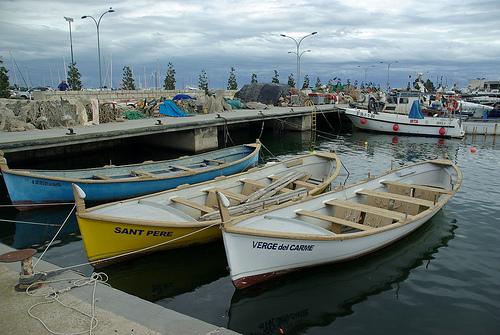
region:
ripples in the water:
[414, 245, 499, 307]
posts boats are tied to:
[7, 244, 51, 291]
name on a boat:
[98, 219, 185, 241]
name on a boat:
[249, 233, 321, 255]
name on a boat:
[25, 177, 72, 189]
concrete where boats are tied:
[3, 270, 78, 319]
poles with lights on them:
[268, 26, 319, 88]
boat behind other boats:
[341, 100, 467, 144]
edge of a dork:
[163, 314, 171, 331]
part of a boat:
[304, 262, 306, 267]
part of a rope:
[47, 291, 64, 317]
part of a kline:
[252, 229, 303, 299]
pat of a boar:
[268, 188, 292, 224]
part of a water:
[276, 270, 301, 315]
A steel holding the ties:
[2, 245, 52, 305]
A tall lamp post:
[75, 5, 121, 96]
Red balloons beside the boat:
[338, 114, 452, 141]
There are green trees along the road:
[202, 65, 315, 95]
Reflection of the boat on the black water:
[218, 287, 378, 332]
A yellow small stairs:
[307, 95, 325, 139]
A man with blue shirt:
[51, 75, 83, 102]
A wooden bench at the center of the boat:
[312, 193, 417, 233]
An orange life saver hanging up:
[436, 92, 468, 121]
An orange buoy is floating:
[465, 142, 485, 156]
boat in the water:
[232, 117, 264, 163]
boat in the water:
[416, 101, 467, 151]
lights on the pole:
[273, 19, 321, 46]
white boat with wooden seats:
[216, 128, 468, 281]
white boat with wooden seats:
[209, 139, 475, 288]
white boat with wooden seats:
[210, 120, 475, 289]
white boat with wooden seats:
[206, 135, 466, 294]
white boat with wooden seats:
[204, 126, 472, 296]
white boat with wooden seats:
[204, 136, 474, 293]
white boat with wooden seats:
[206, 123, 481, 294]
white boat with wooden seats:
[204, 122, 471, 300]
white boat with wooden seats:
[209, 130, 481, 292]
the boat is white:
[215, 153, 462, 292]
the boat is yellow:
[71, 142, 338, 270]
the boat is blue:
[0, 138, 266, 215]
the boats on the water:
[2, 88, 499, 332]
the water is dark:
[3, 111, 499, 333]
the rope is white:
[26, 270, 111, 334]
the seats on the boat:
[215, 150, 462, 292]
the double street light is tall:
[81, 5, 116, 89]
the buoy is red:
[391, 121, 399, 132]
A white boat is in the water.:
[217, 164, 480, 312]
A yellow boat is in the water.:
[66, 147, 346, 289]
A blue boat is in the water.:
[5, 136, 265, 221]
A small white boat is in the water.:
[341, 93, 468, 138]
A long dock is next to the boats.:
[7, 108, 358, 163]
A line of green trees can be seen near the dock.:
[2, 60, 374, 91]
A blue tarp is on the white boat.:
[403, 98, 428, 119]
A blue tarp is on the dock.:
[155, 97, 184, 116]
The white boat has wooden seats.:
[293, 206, 368, 228]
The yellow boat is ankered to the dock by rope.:
[30, 200, 85, 267]